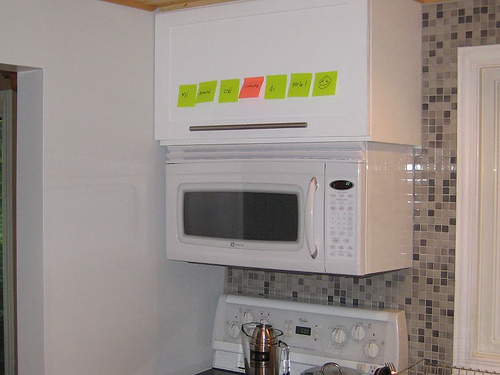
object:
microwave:
[163, 143, 415, 278]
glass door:
[177, 183, 301, 246]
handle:
[305, 177, 318, 260]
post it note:
[177, 84, 197, 107]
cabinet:
[151, 0, 423, 146]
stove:
[188, 293, 410, 375]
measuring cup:
[242, 321, 291, 374]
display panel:
[294, 325, 313, 337]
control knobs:
[351, 324, 366, 341]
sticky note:
[196, 80, 217, 103]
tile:
[420, 7, 454, 374]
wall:
[150, 9, 456, 375]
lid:
[300, 363, 359, 375]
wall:
[37, 6, 150, 375]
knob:
[228, 323, 240, 338]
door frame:
[0, 69, 19, 375]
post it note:
[218, 78, 239, 104]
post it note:
[264, 73, 288, 100]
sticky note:
[239, 76, 264, 98]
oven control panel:
[216, 302, 390, 367]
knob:
[241, 310, 254, 324]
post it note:
[287, 72, 311, 98]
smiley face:
[317, 75, 331, 89]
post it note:
[311, 71, 338, 97]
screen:
[295, 326, 312, 336]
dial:
[330, 328, 345, 344]